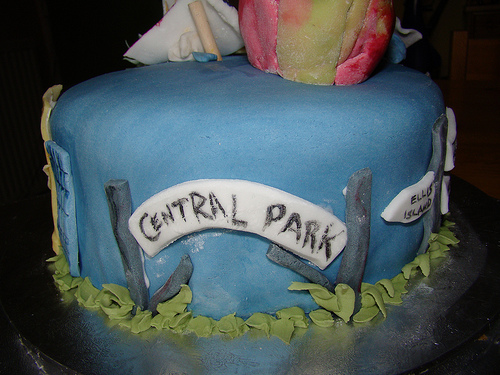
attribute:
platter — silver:
[21, 271, 78, 363]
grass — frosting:
[104, 302, 257, 338]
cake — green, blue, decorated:
[52, 71, 460, 329]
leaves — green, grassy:
[43, 220, 478, 334]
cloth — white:
[117, 5, 240, 69]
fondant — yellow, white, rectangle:
[133, 1, 409, 88]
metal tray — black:
[6, 191, 499, 372]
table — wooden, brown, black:
[6, 73, 499, 374]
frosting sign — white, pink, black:
[131, 178, 348, 263]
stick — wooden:
[97, 178, 194, 299]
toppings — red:
[365, 7, 407, 81]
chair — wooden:
[445, 27, 498, 83]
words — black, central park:
[133, 174, 459, 253]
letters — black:
[405, 183, 443, 218]